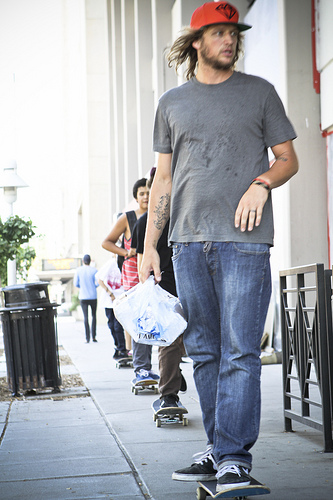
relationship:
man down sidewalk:
[137, 0, 303, 493] [4, 319, 332, 497]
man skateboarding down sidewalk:
[137, 0, 303, 493] [4, 319, 332, 497]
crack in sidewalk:
[88, 386, 159, 494] [4, 319, 332, 497]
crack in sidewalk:
[5, 469, 137, 487] [4, 319, 332, 497]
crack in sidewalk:
[2, 397, 27, 443] [4, 319, 332, 497]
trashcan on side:
[2, 279, 69, 409] [0, 323, 88, 399]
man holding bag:
[137, 0, 303, 493] [111, 271, 190, 355]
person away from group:
[73, 249, 102, 344] [98, 0, 301, 495]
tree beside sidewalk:
[2, 214, 44, 288] [4, 319, 332, 497]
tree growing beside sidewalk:
[2, 214, 44, 288] [4, 319, 332, 497]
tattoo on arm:
[153, 191, 176, 232] [139, 89, 184, 288]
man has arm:
[137, 0, 303, 493] [139, 89, 184, 288]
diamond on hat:
[215, 0, 240, 23] [186, 0, 250, 40]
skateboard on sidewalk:
[192, 464, 269, 498] [4, 319, 332, 497]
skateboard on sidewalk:
[152, 393, 194, 431] [4, 319, 332, 497]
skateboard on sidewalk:
[129, 373, 163, 400] [4, 319, 332, 497]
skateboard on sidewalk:
[110, 351, 135, 367] [4, 319, 332, 497]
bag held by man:
[111, 271, 190, 355] [137, 0, 303, 493]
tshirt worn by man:
[150, 69, 305, 253] [137, 0, 301, 490]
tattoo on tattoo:
[153, 191, 176, 232] [151, 191, 172, 235]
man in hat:
[137, 0, 303, 493] [189, 0, 253, 35]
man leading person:
[137, 0, 303, 493] [130, 167, 192, 412]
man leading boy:
[137, 0, 303, 493] [100, 175, 162, 383]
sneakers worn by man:
[170, 449, 254, 491] [137, 0, 301, 490]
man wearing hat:
[137, 0, 303, 493] [186, 0, 250, 40]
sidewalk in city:
[4, 319, 332, 497] [2, 1, 332, 495]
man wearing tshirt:
[137, 0, 303, 493] [150, 68, 299, 252]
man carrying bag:
[137, 0, 303, 493] [111, 271, 190, 355]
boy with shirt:
[100, 175, 181, 383] [121, 207, 154, 290]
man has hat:
[137, 0, 303, 493] [186, 0, 250, 40]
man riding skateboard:
[137, 0, 303, 493] [192, 464, 269, 498]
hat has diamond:
[186, 0, 250, 40] [215, 2, 240, 23]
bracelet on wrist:
[252, 175, 272, 200] [251, 171, 280, 196]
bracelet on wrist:
[255, 175, 277, 188] [251, 171, 280, 196]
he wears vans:
[139, 0, 311, 491] [165, 450, 261, 490]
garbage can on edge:
[2, 282, 64, 395] [0, 311, 82, 411]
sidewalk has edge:
[4, 319, 332, 497] [0, 311, 82, 411]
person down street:
[73, 247, 108, 352] [2, 303, 327, 463]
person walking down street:
[73, 247, 108, 352] [2, 303, 327, 463]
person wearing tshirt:
[73, 247, 108, 352] [74, 262, 99, 302]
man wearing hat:
[137, 0, 303, 493] [189, 0, 253, 35]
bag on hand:
[111, 271, 190, 355] [137, 246, 166, 293]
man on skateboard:
[137, 0, 303, 493] [192, 464, 269, 498]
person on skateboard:
[137, 0, 303, 493] [192, 464, 269, 498]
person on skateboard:
[130, 167, 194, 428] [152, 393, 194, 431]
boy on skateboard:
[100, 175, 162, 383] [129, 373, 163, 400]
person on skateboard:
[102, 246, 136, 375] [110, 351, 135, 367]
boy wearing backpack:
[100, 175, 162, 383] [115, 210, 153, 276]